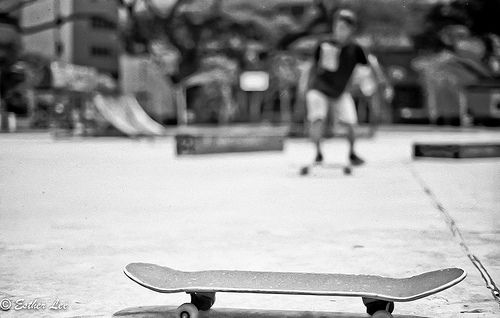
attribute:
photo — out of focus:
[0, 1, 497, 201]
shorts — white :
[299, 81, 362, 130]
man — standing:
[306, 17, 386, 170]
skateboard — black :
[120, 247, 475, 314]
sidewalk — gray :
[281, 159, 416, 244]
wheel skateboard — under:
[333, 165, 360, 184]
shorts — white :
[306, 89, 365, 128]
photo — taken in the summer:
[5, 4, 499, 312]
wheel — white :
[357, 300, 389, 317]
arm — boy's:
[273, 30, 306, 73]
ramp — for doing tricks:
[410, 136, 497, 181]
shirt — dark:
[306, 36, 371, 99]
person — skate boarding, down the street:
[277, 7, 392, 182]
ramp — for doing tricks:
[35, 55, 228, 143]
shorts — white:
[306, 81, 381, 141]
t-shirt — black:
[311, 35, 365, 95]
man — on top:
[313, 7, 376, 186]